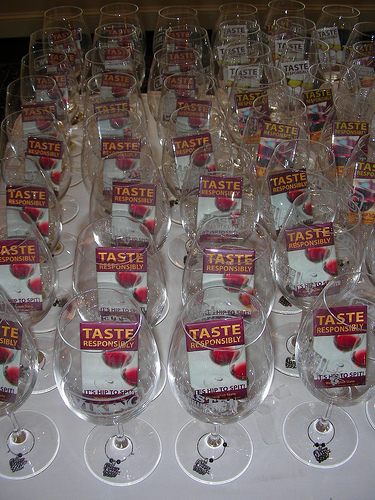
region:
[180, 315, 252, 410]
taste responsibly packet in a wineglass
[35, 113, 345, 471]
many wineglasses in a row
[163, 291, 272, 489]
clear glass wine glass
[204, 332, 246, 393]
red wine in two wine glasses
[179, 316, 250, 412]
pamphlet with yellow text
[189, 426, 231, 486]
wine glass charm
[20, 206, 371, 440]
wineglasses in a row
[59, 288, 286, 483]
wine glasses with charms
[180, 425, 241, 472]
charm on base of wineglass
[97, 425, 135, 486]
blue and silver wineglass charm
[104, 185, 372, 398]
wine glasses with cards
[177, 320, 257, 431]
instructions for a wine tasting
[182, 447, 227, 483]
a blue logo on glass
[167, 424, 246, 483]
the wine glass is clear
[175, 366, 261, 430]
the logo is etched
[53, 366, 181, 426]
the logo is viking cruise lines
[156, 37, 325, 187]
the chocolate bars have flavors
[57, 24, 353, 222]
different flavors of chocolate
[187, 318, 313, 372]
the words taste responsibly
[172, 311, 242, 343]
the font is yellow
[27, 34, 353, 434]
a table with wine glasses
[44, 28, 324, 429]
a table with clean wine glasses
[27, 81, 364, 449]
taste responsibly cards inside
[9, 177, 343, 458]
wine glass with cards inside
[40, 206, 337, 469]
wine glasses for tasting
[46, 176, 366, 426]
wine glasses for wine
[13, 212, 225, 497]
wine glasses with charms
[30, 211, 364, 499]
charms on wine glasses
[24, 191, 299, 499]
wine glasses on a white table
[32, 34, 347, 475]
a table full of wine glasses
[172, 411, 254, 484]
the base of a glass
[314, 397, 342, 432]
the stem of a wine glass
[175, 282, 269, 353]
the mouth of a glass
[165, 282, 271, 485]
a clear wine glass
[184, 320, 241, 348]
yellow writing on the card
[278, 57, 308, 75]
black writing on the card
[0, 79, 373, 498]
a white table under the glasses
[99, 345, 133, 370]
a piece of watermelon on the card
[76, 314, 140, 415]
a card in the glass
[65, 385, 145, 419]
white writing on the glass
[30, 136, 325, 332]
table set for beer-pong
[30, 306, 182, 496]
red wine glass with note in it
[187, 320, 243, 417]
picture of red wine glass with wine in it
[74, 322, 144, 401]
note in red wine glass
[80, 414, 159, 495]
base of a red wine glass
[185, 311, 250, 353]
taste responsibly note in glass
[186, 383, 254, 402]
wine tasters hint to wine tasting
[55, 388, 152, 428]
a Viking red wine glass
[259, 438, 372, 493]
table to stand glasses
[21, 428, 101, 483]
space between the red wine glasses